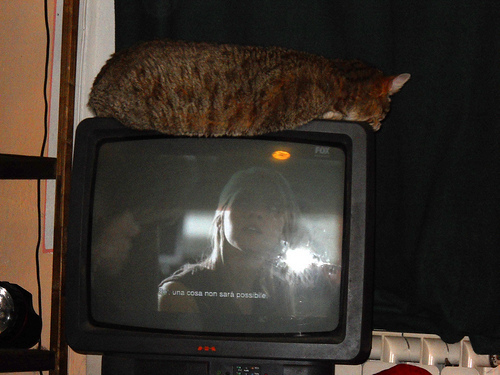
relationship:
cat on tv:
[86, 37, 411, 139] [66, 118, 363, 360]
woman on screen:
[154, 167, 309, 325] [55, 103, 376, 369]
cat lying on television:
[86, 37, 411, 139] [60, 118, 367, 374]